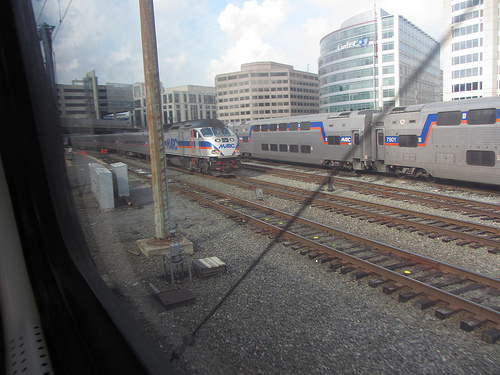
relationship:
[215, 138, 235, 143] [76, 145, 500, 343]
black writing on tracks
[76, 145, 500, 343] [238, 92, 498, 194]
tracks in front of engine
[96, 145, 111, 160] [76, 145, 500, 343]
cones around tracks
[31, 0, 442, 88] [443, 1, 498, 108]
clouds over building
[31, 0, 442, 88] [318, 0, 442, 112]
clouds over building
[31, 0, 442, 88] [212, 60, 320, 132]
clouds over building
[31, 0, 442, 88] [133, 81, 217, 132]
clouds over building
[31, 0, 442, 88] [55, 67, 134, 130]
clouds over building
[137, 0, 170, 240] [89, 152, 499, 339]
pole standing next to track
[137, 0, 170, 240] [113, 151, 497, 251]
pole standing next to track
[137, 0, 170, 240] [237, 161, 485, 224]
pole standing next to track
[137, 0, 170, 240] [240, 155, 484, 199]
pole standing next to track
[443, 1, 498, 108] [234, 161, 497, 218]
building near track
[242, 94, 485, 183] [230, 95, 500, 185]
double decker on car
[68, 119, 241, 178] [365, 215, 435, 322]
train car in track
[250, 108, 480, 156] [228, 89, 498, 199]
windows attached to side of train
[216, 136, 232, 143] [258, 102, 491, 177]
black writing on train